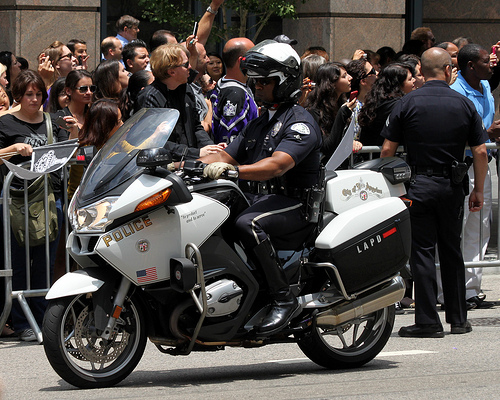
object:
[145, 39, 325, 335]
officer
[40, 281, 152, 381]
front tire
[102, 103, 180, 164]
windshield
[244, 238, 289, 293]
knee-high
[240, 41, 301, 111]
black and white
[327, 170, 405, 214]
cargo box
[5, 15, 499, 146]
crowd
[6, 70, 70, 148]
people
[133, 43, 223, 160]
man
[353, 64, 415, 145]
woman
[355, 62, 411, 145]
black hair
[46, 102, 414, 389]
bike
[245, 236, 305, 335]
black boots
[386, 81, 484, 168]
black shirt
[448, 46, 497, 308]
man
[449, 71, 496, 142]
blue shirt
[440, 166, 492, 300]
white pants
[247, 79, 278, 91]
dark sunglasses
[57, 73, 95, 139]
woman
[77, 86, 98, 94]
dark sunglasses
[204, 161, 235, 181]
beige gloves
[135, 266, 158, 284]
american flag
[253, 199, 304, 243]
white stripe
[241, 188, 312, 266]
pants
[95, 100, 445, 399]
road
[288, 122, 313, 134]
patch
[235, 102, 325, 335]
uniform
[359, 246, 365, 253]
white letters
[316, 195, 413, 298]
black case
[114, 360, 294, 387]
shadow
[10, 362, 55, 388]
pavement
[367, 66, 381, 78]
sun glasses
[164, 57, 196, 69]
sunglasses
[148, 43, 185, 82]
hair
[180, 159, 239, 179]
handlebar